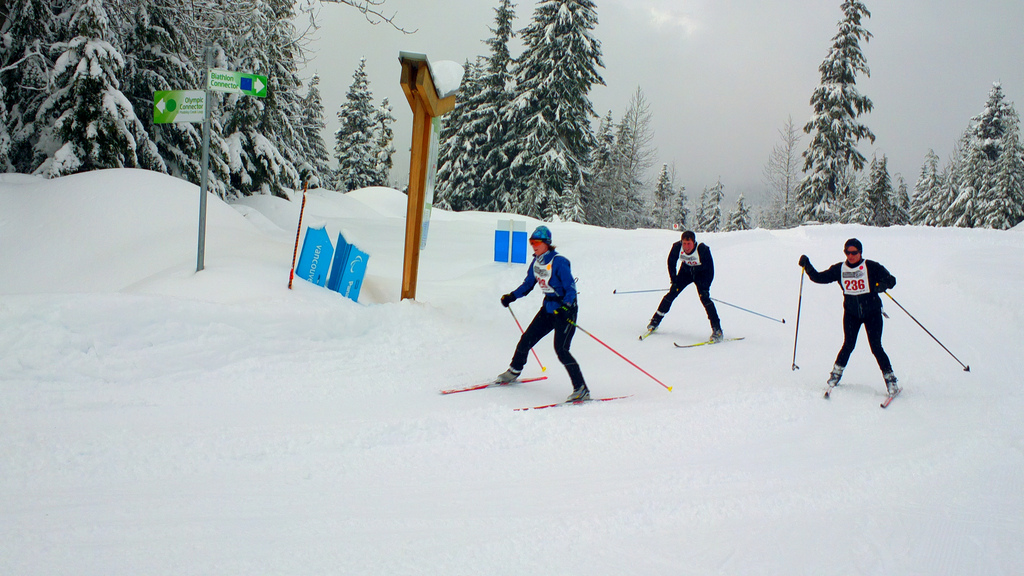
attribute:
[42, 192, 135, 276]
snow — white